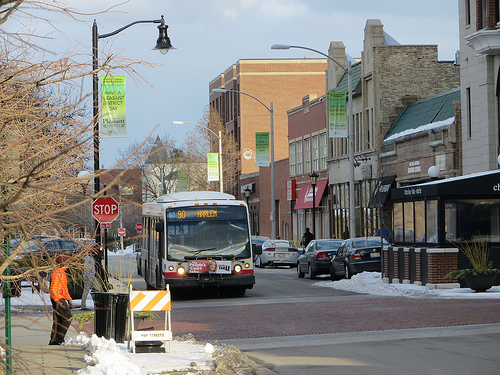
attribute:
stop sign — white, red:
[92, 190, 119, 224]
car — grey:
[243, 232, 304, 286]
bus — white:
[143, 187, 262, 295]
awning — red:
[295, 182, 329, 210]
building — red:
[280, 93, 330, 245]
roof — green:
[387, 86, 456, 146]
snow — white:
[379, 111, 459, 141]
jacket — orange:
[51, 264, 73, 302]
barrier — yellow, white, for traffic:
[122, 283, 178, 355]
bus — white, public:
[142, 192, 264, 304]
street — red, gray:
[178, 294, 498, 372]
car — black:
[332, 235, 386, 282]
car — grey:
[295, 236, 344, 279]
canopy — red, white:
[291, 173, 327, 215]